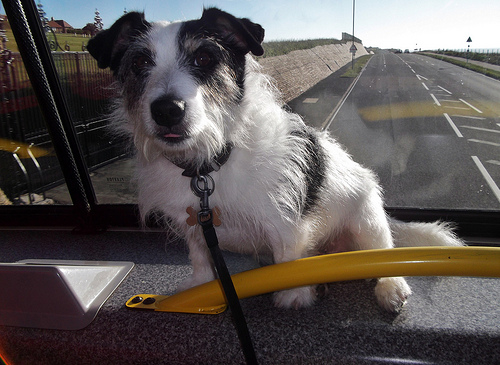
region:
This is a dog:
[75, 1, 435, 294]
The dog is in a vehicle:
[59, 10, 422, 295]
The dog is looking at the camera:
[75, 18, 285, 156]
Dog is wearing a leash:
[182, 152, 255, 362]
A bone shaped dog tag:
[174, 200, 229, 233]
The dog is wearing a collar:
[159, 133, 252, 171]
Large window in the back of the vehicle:
[55, 1, 480, 198]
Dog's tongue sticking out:
[153, 127, 189, 144]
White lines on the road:
[396, 35, 497, 200]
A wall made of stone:
[284, 44, 345, 88]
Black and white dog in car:
[97, 5, 467, 307]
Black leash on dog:
[203, 213, 247, 359]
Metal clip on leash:
[194, 178, 208, 213]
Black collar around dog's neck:
[170, 152, 227, 174]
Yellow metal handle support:
[140, 241, 497, 308]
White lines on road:
[409, 49, 499, 208]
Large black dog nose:
[154, 95, 191, 125]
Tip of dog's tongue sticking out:
[165, 132, 181, 140]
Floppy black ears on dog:
[82, 4, 271, 57]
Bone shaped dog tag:
[185, 203, 226, 228]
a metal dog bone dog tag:
[184, 205, 221, 229]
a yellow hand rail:
[127, 248, 499, 313]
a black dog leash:
[195, 176, 255, 361]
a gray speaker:
[1, 255, 133, 330]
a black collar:
[177, 144, 235, 179]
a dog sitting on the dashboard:
[82, 9, 459, 307]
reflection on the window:
[359, 95, 499, 122]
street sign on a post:
[463, 36, 472, 63]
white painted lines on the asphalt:
[394, 50, 498, 197]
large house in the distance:
[47, 19, 99, 33]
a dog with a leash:
[63, 6, 383, 308]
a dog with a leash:
[78, 10, 326, 264]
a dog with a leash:
[78, 7, 340, 319]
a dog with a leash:
[100, 31, 352, 341]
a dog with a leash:
[57, 18, 310, 298]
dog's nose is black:
[142, 89, 196, 141]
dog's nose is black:
[140, 89, 201, 146]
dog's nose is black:
[131, 89, 197, 135]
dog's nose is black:
[135, 74, 207, 130]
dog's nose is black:
[133, 76, 214, 138]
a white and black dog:
[88, 5, 463, 308]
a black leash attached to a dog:
[191, 177, 253, 364]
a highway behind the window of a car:
[283, 44, 498, 210]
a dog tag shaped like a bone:
[184, 205, 222, 227]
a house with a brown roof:
[46, 16, 73, 35]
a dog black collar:
[167, 144, 236, 178]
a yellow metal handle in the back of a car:
[126, 244, 498, 327]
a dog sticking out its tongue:
[156, 128, 188, 143]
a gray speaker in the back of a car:
[1, 256, 135, 330]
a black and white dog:
[85, 4, 466, 316]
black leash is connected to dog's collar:
[85, 6, 467, 364]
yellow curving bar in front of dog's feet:
[87, 6, 498, 315]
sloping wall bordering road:
[260, 40, 498, 212]